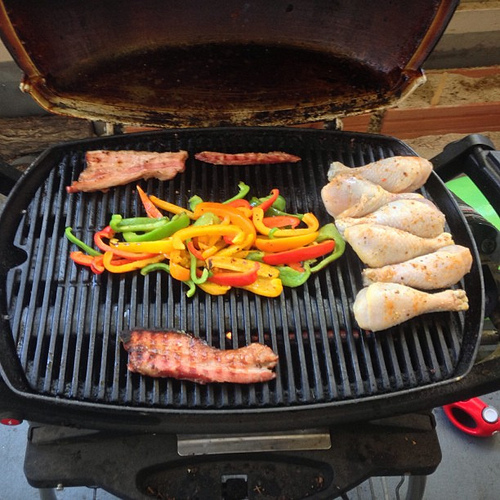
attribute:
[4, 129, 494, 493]
grill — black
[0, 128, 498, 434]
grill — iron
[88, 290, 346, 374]
meat — single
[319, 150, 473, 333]
legs — raw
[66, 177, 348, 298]
peppers — sliced, three colors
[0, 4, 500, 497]
grill — metal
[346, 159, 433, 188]
chicken — raw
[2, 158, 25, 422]
grill handle — black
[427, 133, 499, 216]
grill handle — black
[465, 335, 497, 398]
grill handle — black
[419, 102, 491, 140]
step — brown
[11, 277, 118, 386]
grill — black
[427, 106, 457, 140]
ground — grey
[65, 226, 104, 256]
food — green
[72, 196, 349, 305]
food — red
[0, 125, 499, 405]
grill — black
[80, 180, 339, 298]
peppers — green, yellow, and red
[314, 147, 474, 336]
meat — grilled